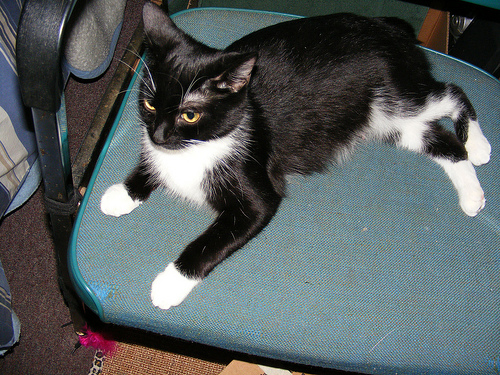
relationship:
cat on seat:
[116, 14, 455, 222] [89, 13, 497, 358]